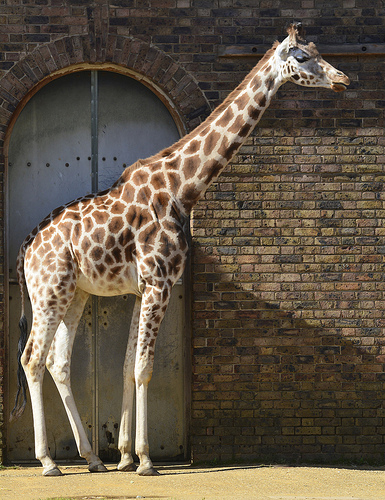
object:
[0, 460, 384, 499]
ground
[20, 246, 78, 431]
legs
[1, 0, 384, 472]
brick wall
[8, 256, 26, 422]
tail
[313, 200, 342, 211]
dark brick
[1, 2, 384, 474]
building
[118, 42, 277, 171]
giraffe mane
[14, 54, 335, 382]
spots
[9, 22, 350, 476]
giraffe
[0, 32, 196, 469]
archway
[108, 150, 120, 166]
rivet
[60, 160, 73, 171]
rivet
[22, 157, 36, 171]
rivet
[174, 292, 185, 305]
rivet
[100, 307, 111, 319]
rivet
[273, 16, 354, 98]
spotted head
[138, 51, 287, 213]
neck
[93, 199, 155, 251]
skin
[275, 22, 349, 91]
giraffe head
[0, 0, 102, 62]
bricks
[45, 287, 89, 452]
leg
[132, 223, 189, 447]
leg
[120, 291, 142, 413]
leg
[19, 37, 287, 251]
back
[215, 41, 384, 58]
wood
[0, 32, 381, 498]
sunshine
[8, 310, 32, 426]
hair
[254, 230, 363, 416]
brick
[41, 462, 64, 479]
hoofs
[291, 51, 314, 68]
eye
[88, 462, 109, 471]
hoof